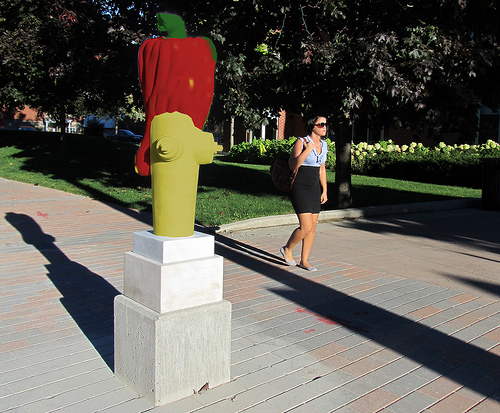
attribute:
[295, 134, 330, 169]
shirt — gray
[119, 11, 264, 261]
statue — red, green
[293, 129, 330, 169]
shirt — Blue 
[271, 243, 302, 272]
shoe — light blue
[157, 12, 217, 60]
piece — green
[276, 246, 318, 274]
flats — gray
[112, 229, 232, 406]
statue pedestal — square, light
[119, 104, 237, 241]
hydrant — yellow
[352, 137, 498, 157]
flowers — yellow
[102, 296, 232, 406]
base — Concrete 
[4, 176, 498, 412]
walkway — light grey, brick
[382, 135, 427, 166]
flowers — white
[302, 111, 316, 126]
hair — dark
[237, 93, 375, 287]
woman — Walking 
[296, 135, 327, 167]
top — light blue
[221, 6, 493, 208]
tree — behind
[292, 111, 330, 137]
hair — dark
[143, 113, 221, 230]
hydrant — yellow, fire hydrant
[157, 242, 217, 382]
blocks — concrete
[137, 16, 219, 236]
statue — green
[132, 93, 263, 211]
statue — red, yellow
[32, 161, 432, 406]
walkway — brick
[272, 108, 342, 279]
woman — black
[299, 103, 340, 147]
hair — short 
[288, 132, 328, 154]
shirt — blue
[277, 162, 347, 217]
skirt — black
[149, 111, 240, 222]
bottom — yellow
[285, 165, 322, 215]
skirt — black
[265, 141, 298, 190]
bag — brown 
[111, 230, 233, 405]
base — white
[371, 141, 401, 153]
flowers — white